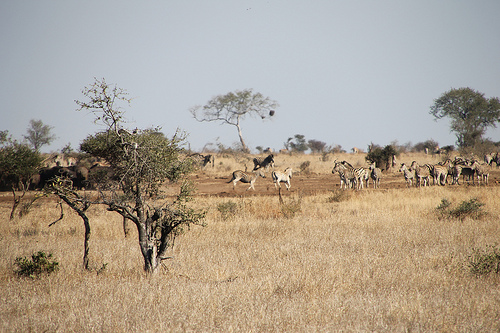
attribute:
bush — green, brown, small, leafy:
[437, 196, 489, 219]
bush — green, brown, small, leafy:
[467, 245, 499, 278]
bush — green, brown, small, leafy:
[13, 251, 59, 277]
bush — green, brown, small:
[330, 188, 352, 203]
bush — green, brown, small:
[274, 197, 301, 218]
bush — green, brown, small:
[218, 200, 238, 221]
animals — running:
[223, 153, 499, 188]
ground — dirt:
[2, 151, 498, 332]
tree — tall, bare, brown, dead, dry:
[189, 91, 281, 152]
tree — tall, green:
[428, 85, 499, 144]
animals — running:
[225, 165, 294, 190]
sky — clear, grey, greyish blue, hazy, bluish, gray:
[0, 1, 498, 154]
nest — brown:
[129, 141, 140, 148]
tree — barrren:
[86, 80, 212, 273]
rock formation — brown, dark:
[42, 155, 73, 166]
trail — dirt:
[2, 172, 499, 196]